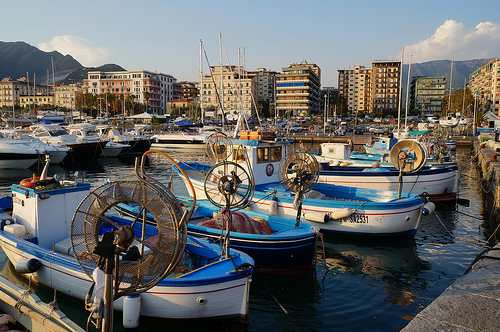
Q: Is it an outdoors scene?
A: Yes, it is outdoors.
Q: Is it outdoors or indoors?
A: It is outdoors.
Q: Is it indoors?
A: No, it is outdoors.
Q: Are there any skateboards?
A: No, there are no skateboards.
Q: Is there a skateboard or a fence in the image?
A: No, there are no skateboards or fences.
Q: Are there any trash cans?
A: No, there are no trash cans.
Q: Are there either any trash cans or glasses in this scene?
A: No, there are no trash cans or glasses.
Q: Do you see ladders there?
A: No, there are no ladders.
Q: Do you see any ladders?
A: No, there are no ladders.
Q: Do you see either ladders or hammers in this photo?
A: No, there are no ladders or hammers.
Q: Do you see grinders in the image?
A: No, there are no grinders.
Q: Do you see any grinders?
A: No, there are no grinders.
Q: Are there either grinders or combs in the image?
A: No, there are no grinders or combs.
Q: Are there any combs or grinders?
A: No, there are no grinders or combs.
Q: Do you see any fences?
A: No, there are no fences.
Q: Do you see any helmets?
A: No, there are no helmets.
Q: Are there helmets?
A: No, there are no helmets.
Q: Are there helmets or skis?
A: No, there are no helmets or skis.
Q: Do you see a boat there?
A: Yes, there is a boat.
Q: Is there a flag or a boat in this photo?
A: Yes, there is a boat.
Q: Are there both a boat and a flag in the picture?
A: No, there is a boat but no flags.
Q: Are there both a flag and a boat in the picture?
A: No, there is a boat but no flags.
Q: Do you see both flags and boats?
A: No, there is a boat but no flags.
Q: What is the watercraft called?
A: The watercraft is a boat.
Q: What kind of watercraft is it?
A: The watercraft is a boat.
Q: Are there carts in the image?
A: No, there are no carts.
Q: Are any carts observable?
A: No, there are no carts.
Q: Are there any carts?
A: No, there are no carts.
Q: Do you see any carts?
A: No, there are no carts.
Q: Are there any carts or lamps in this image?
A: No, there are no carts or lamps.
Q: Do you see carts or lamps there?
A: No, there are no carts or lamps.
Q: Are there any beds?
A: Yes, there is a bed.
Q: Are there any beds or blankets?
A: Yes, there is a bed.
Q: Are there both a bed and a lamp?
A: No, there is a bed but no lamps.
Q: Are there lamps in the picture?
A: No, there are no lamps.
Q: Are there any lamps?
A: No, there are no lamps.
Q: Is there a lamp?
A: No, there are no lamps.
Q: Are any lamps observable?
A: No, there are no lamps.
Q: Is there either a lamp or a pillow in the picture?
A: No, there are no lamps or pillows.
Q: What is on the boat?
A: The bed is on the boat.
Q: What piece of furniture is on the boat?
A: The piece of furniture is a bed.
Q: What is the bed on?
A: The bed is on the boat.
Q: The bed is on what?
A: The bed is on the boat.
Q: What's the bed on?
A: The bed is on the boat.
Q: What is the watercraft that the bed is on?
A: The watercraft is a boat.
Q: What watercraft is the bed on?
A: The bed is on the boat.